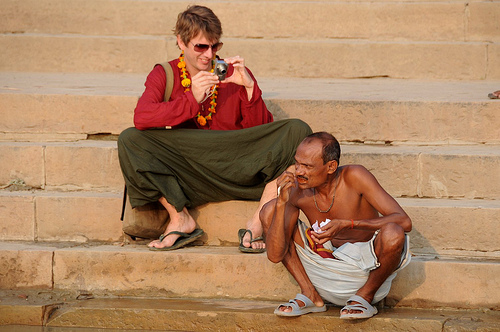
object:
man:
[118, 5, 313, 249]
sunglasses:
[188, 40, 224, 53]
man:
[257, 131, 414, 320]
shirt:
[134, 56, 278, 131]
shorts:
[294, 220, 413, 308]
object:
[314, 217, 334, 233]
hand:
[278, 170, 297, 200]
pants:
[117, 118, 315, 211]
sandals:
[147, 228, 269, 254]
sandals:
[274, 291, 329, 317]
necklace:
[176, 55, 219, 127]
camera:
[213, 60, 229, 82]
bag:
[121, 191, 169, 239]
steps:
[1, 1, 500, 47]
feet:
[145, 212, 266, 250]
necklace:
[310, 184, 339, 214]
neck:
[181, 61, 202, 75]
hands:
[192, 54, 256, 99]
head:
[174, 3, 223, 69]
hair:
[174, 6, 222, 45]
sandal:
[271, 293, 328, 317]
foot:
[277, 298, 325, 313]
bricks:
[420, 143, 500, 199]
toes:
[153, 241, 165, 250]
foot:
[147, 216, 198, 249]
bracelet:
[350, 215, 357, 227]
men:
[115, 5, 414, 322]